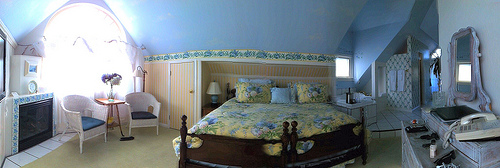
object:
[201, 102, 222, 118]
end table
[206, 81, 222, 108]
lamp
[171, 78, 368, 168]
bed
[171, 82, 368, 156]
flowers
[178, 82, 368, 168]
bed frame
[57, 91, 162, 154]
chairs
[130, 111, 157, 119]
cushions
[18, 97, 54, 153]
fireplace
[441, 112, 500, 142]
phone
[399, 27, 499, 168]
dresser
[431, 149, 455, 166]
sunglasses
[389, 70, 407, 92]
towels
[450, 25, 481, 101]
mirror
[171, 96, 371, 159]
bedspread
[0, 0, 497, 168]
bedroom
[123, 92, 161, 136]
chair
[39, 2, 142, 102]
window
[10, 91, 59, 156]
white trim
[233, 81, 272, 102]
pillow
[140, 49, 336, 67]
wallpaper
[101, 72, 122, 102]
flowers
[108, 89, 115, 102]
vase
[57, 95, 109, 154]
chair